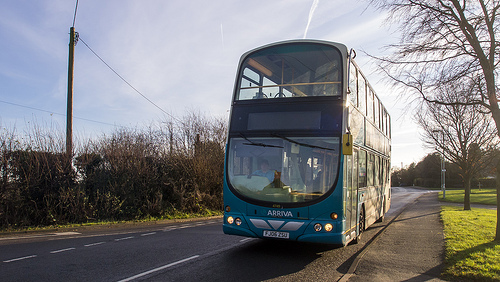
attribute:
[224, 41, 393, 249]
bus — teal, big, green, tall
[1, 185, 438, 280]
road — gray, concrete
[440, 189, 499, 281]
grass — green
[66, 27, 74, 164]
pole — long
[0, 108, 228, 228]
bushes — bare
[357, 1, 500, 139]
tree — bare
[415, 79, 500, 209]
tree — bare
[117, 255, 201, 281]
line — white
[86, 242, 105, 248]
line — white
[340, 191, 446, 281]
sidewalk — grey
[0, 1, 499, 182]
sky — blue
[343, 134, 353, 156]
mirror — yellow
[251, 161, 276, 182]
man — driving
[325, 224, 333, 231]
light — on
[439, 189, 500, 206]
grass — green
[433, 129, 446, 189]
street light — gray